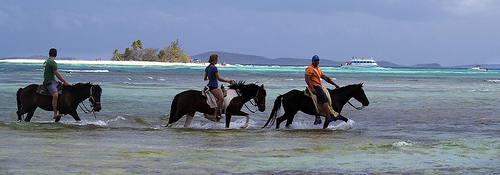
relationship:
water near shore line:
[86, 121, 155, 164] [149, 54, 175, 65]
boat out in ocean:
[343, 54, 402, 78] [338, 70, 405, 97]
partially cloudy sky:
[67, 17, 183, 24] [231, 19, 298, 68]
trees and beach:
[113, 26, 193, 59] [109, 57, 176, 75]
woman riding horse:
[181, 39, 239, 133] [157, 79, 269, 122]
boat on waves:
[343, 54, 402, 78] [333, 63, 377, 75]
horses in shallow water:
[274, 65, 391, 128] [240, 118, 375, 145]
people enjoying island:
[305, 56, 340, 122] [0, 39, 237, 66]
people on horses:
[145, 43, 343, 131] [274, 65, 391, 128]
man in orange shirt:
[18, 46, 80, 120] [295, 55, 329, 106]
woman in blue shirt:
[181, 39, 239, 133] [186, 65, 225, 86]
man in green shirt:
[18, 46, 80, 120] [26, 57, 64, 87]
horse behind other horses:
[157, 79, 269, 122] [274, 65, 391, 128]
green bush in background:
[108, 43, 150, 69] [211, 27, 230, 42]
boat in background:
[343, 54, 402, 78] [211, 27, 230, 42]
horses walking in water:
[274, 65, 391, 128] [264, 124, 354, 154]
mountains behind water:
[182, 43, 285, 59] [86, 121, 155, 164]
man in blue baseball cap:
[18, 46, 80, 120] [294, 45, 327, 67]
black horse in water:
[274, 65, 391, 128] [264, 124, 354, 154]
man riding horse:
[18, 46, 80, 120] [157, 79, 269, 122]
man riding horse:
[18, 46, 80, 120] [258, 78, 374, 119]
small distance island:
[93, 36, 193, 60] [70, 20, 216, 70]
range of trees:
[162, 31, 200, 65] [113, 26, 193, 59]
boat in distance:
[345, 60, 377, 66] [182, 50, 500, 68]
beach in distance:
[0, 59, 230, 67] [208, 47, 215, 52]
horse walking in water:
[157, 79, 269, 122] [264, 124, 354, 154]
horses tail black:
[274, 65, 391, 128] [258, 78, 374, 119]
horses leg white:
[274, 65, 391, 128] [234, 113, 252, 139]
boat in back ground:
[343, 54, 402, 78] [357, 37, 383, 52]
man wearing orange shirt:
[18, 46, 80, 120] [305, 64, 325, 87]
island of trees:
[70, 20, 216, 70] [113, 26, 193, 59]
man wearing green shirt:
[18, 46, 80, 120] [43, 58, 58, 84]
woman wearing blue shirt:
[181, 39, 239, 133] [205, 66, 218, 87]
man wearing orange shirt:
[18, 46, 80, 120] [295, 55, 329, 106]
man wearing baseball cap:
[18, 46, 80, 120] [312, 54, 319, 60]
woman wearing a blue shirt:
[181, 39, 239, 133] [186, 65, 225, 86]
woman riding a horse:
[181, 39, 239, 133] [258, 78, 374, 119]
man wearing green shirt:
[18, 46, 80, 120] [26, 57, 64, 87]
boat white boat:
[345, 60, 377, 66] [343, 54, 402, 78]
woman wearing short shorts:
[181, 39, 239, 133] [203, 79, 227, 95]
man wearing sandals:
[18, 46, 80, 120] [26, 108, 69, 139]